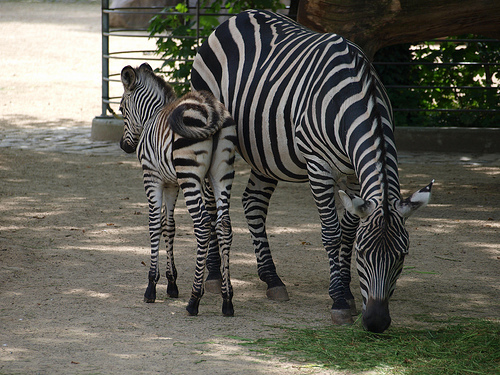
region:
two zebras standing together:
[118, 7, 444, 369]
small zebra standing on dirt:
[60, 54, 256, 331]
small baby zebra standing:
[81, 38, 266, 322]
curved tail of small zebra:
[158, 107, 231, 137]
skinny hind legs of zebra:
[186, 176, 232, 318]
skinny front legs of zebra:
[143, 174, 181, 306]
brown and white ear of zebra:
[120, 64, 139, 96]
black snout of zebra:
[115, 135, 136, 153]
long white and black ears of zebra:
[395, 175, 440, 217]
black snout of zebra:
[368, 297, 389, 327]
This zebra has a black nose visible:
[363, 290, 393, 365]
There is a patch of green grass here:
[424, 330, 434, 352]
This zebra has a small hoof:
[221, 300, 251, 342]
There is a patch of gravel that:
[45, 218, 69, 298]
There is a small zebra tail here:
[163, 112, 205, 164]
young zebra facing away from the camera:
[116, 60, 239, 317]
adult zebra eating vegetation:
[187, 7, 439, 334]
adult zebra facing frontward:
[188, 8, 436, 335]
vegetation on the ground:
[242, 318, 498, 374]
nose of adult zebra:
[358, 295, 392, 337]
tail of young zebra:
[168, 93, 225, 141]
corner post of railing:
[95, 3, 113, 115]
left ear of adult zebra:
[399, 179, 435, 221]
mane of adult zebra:
[363, 68, 393, 240]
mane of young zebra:
[139, 65, 171, 102]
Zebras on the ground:
[98, 7, 445, 339]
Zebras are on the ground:
[102, 8, 437, 336]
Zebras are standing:
[117, 7, 438, 335]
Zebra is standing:
[184, 7, 441, 331]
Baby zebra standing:
[107, 55, 248, 321]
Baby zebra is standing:
[112, 57, 251, 319]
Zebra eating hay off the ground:
[183, 8, 434, 335]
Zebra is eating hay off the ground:
[182, 7, 439, 337]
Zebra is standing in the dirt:
[183, 7, 440, 326]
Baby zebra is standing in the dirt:
[112, 56, 263, 323]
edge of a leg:
[244, 336, 249, 351]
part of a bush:
[457, 83, 462, 92]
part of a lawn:
[313, 342, 317, 345]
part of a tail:
[282, 211, 301, 261]